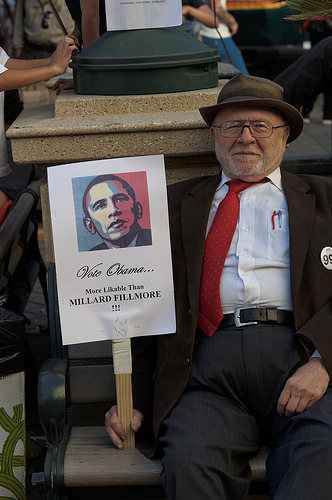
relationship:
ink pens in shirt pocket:
[268, 209, 287, 232] [271, 211, 292, 265]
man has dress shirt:
[151, 71, 329, 498] [213, 172, 290, 312]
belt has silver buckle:
[204, 305, 294, 330] [231, 306, 258, 329]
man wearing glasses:
[151, 71, 329, 498] [211, 120, 289, 138]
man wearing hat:
[151, 71, 329, 498] [198, 71, 309, 117]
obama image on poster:
[65, 171, 154, 253] [38, 154, 179, 345]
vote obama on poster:
[71, 260, 158, 281] [38, 154, 179, 345]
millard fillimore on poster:
[68, 290, 163, 308] [38, 154, 179, 345]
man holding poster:
[151, 71, 329, 498] [38, 154, 179, 345]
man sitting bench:
[151, 71, 329, 498] [39, 356, 331, 489]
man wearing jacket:
[151, 71, 329, 498] [153, 174, 324, 400]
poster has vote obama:
[38, 154, 179, 345] [71, 260, 158, 281]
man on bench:
[151, 71, 329, 498] [39, 356, 331, 489]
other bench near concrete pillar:
[0, 173, 47, 325] [8, 86, 221, 170]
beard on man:
[214, 136, 286, 181] [151, 71, 329, 498]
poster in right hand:
[38, 154, 179, 345] [105, 406, 142, 446]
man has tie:
[151, 71, 329, 498] [200, 179, 260, 330]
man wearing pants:
[151, 71, 329, 498] [166, 327, 329, 498]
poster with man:
[38, 154, 179, 345] [151, 71, 329, 498]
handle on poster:
[113, 374, 137, 447] [38, 154, 179, 345]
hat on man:
[198, 71, 309, 117] [151, 71, 329, 498]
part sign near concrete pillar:
[97, 2, 188, 30] [8, 86, 221, 170]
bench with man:
[39, 356, 331, 489] [151, 71, 329, 498]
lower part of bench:
[43, 431, 330, 480] [39, 356, 331, 489]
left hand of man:
[275, 360, 331, 416] [151, 71, 329, 498]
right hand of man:
[105, 406, 142, 446] [151, 71, 329, 498]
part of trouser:
[191, 400, 240, 451] [275, 31, 328, 105]